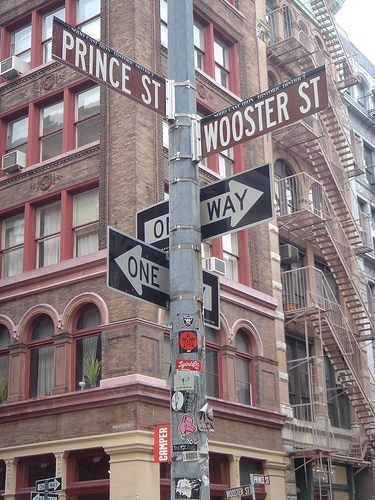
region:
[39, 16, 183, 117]
The sign is brown and white.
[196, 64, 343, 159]
The sign is brown and white.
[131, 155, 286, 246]
The sign is black and white.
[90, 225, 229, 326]
The sign is black and white.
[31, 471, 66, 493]
The sign is black and white.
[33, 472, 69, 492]
The sign has an arrow on it.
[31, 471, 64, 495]
The arrow is pointing right.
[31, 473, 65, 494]
The arrow is white.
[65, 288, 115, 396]
The window is arced at the top.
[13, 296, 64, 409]
The window is arced at the top.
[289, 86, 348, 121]
a sign that says street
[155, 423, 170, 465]
a red and white camper sign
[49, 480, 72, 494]
a arrow pointing to the righ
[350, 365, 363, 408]
stairs at the building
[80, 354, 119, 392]
a green plant on a window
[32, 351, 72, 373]
a window on a building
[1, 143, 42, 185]
a air conditioner to the building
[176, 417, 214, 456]
stickers on a pole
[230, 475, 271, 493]
signs to tell you were th go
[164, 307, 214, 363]
a big pole near building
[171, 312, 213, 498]
Assorted stickers on pole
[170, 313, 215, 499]
Graffiti stickers on street pole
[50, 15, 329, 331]
Street signs on pole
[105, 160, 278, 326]
One way signs on pole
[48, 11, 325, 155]
Street signs on pole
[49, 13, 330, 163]
Brown signs on street pole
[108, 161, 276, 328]
Black and white signs on street pole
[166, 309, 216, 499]
Random stickers on a street pole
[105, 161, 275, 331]
Two one way signs on pole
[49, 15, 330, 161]
Two street name signs on pole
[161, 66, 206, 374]
Pole is grey color.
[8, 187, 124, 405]
Building brown color.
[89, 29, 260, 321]
Boards are attached to the pole.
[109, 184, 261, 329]
Arrow sign is black and white color.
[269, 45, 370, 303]
Steps are attached to the building wall.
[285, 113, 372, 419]
Steps are brown color.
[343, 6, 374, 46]
Sky is white color.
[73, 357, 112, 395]
Plant is in window sill.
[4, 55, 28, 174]
AC are fixed to the window.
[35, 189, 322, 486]
Day time picture.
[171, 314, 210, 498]
many stickers are on the pole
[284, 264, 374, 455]
a ladder on the building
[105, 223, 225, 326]
a one way street sign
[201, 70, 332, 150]
a wooster street sign in brown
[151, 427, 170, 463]
the word camper in white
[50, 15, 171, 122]
a sign saying prince st.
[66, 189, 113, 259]
a window on the building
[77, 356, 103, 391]
a green plant near the window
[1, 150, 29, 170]
an air conditioner sticking out the window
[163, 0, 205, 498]
the street pole is gray